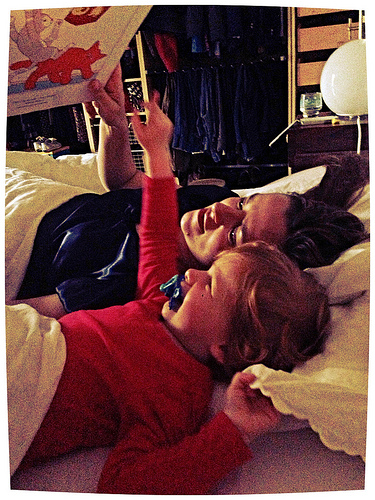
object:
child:
[4, 242, 332, 495]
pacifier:
[160, 274, 182, 310]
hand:
[131, 100, 175, 150]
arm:
[136, 148, 178, 301]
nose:
[184, 268, 208, 284]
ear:
[209, 341, 225, 363]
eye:
[207, 275, 213, 297]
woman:
[3, 61, 369, 320]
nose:
[211, 202, 240, 225]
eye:
[229, 222, 241, 247]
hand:
[84, 62, 126, 127]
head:
[160, 241, 331, 368]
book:
[6, 4, 154, 119]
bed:
[2, 150, 371, 494]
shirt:
[20, 176, 252, 494]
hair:
[283, 149, 370, 271]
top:
[12, 182, 244, 316]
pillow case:
[240, 290, 374, 462]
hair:
[214, 241, 331, 382]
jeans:
[197, 65, 215, 153]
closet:
[134, 7, 296, 185]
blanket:
[4, 147, 108, 476]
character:
[25, 40, 109, 88]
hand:
[224, 368, 283, 437]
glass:
[300, 93, 323, 118]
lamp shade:
[319, 36, 368, 116]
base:
[357, 115, 362, 155]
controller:
[269, 116, 334, 147]